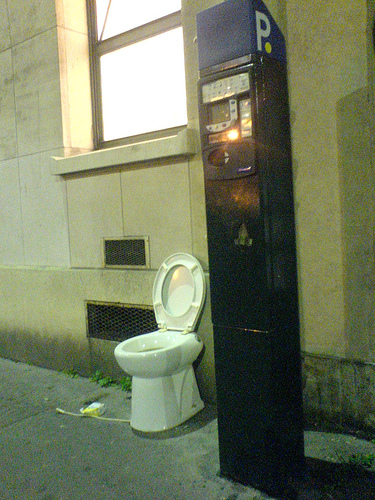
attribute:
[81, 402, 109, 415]
box — cigarettes, yellow, white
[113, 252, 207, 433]
toilet — broken, white, porcelain, tall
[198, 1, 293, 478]
meter — machine, black, blue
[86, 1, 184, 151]
window — clear, metal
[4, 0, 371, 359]
building — cement, white, gray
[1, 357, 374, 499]
sidewalk — cement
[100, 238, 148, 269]
vent — small, open, black, white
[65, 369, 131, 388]
weeds — small, green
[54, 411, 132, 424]
hose — narrow, white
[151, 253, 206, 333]
lid — plastic